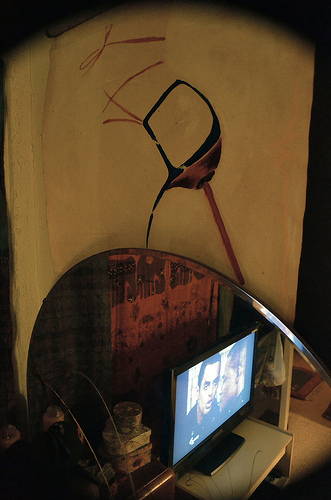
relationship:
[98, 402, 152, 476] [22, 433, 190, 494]
box on table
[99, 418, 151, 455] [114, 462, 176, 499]
box on table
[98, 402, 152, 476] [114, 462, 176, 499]
box on table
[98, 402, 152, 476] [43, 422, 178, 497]
box on table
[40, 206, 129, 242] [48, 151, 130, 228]
part of a wall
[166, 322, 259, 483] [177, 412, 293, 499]
television on table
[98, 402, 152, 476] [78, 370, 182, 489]
box beside televison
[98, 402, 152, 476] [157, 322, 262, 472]
box beside television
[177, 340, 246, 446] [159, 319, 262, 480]
two men on tv screen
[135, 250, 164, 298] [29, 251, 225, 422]
elephant on fabric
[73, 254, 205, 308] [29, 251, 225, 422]
elephant on fabric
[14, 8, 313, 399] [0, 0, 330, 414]
artwork on wall